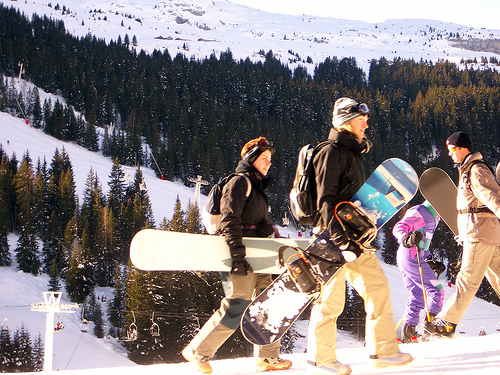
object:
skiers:
[180, 136, 293, 374]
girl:
[391, 199, 454, 345]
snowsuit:
[391, 199, 445, 326]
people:
[392, 199, 458, 343]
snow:
[0, 113, 499, 371]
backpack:
[290, 144, 323, 227]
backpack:
[203, 177, 229, 236]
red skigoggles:
[259, 139, 270, 148]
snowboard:
[129, 229, 317, 276]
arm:
[220, 181, 248, 260]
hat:
[332, 97, 363, 128]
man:
[422, 131, 499, 339]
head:
[332, 97, 370, 145]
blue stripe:
[385, 158, 419, 193]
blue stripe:
[354, 182, 399, 226]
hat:
[445, 131, 472, 151]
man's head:
[445, 131, 477, 164]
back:
[243, 155, 423, 351]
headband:
[243, 139, 276, 165]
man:
[288, 97, 412, 375]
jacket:
[312, 128, 373, 245]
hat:
[242, 139, 276, 165]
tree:
[34, 12, 43, 40]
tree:
[127, 104, 144, 166]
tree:
[243, 57, 252, 112]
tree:
[314, 63, 322, 81]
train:
[418, 126, 500, 341]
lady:
[181, 135, 293, 374]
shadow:
[371, 350, 499, 374]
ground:
[0, 332, 500, 374]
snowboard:
[240, 157, 419, 347]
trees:
[10, 158, 43, 276]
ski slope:
[2, 106, 497, 373]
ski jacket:
[219, 160, 275, 258]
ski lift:
[121, 323, 138, 342]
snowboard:
[418, 167, 500, 301]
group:
[180, 97, 500, 373]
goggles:
[337, 103, 372, 120]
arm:
[316, 152, 350, 245]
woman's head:
[240, 135, 273, 177]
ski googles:
[244, 139, 273, 159]